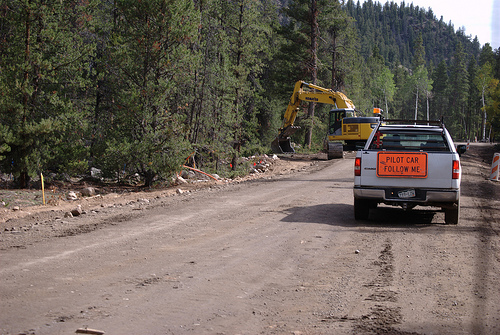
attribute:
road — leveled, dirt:
[94, 159, 492, 334]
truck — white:
[345, 111, 466, 229]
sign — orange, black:
[374, 148, 431, 179]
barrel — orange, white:
[489, 148, 499, 182]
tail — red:
[350, 154, 364, 178]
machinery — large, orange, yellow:
[276, 72, 377, 158]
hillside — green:
[3, 2, 497, 80]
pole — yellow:
[36, 171, 48, 206]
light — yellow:
[372, 103, 380, 115]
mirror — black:
[457, 140, 468, 157]